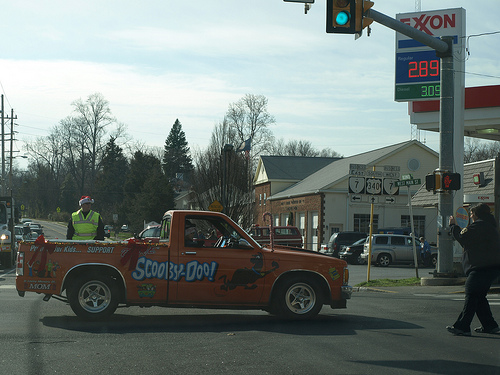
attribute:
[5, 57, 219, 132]
clouds — white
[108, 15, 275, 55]
clouds — white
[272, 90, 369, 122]
clouds — white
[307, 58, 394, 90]
clouds — white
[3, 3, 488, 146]
sky — blue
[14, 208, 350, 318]
truck — white, orange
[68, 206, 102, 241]
safety vest — yellow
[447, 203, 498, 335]
woman — taking picture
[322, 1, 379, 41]
signal light — green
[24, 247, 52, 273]
bow — red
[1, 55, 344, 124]
cloud — white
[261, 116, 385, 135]
cloud — white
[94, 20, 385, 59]
cloud — white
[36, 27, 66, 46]
cloud — white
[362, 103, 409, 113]
cloud — white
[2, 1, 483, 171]
sky — blue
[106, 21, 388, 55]
cloud — white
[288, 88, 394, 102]
cloud — white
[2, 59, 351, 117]
cloud — white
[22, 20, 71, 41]
cloud — white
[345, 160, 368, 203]
sign — black, white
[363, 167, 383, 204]
sign — black, white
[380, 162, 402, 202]
sign — black, white